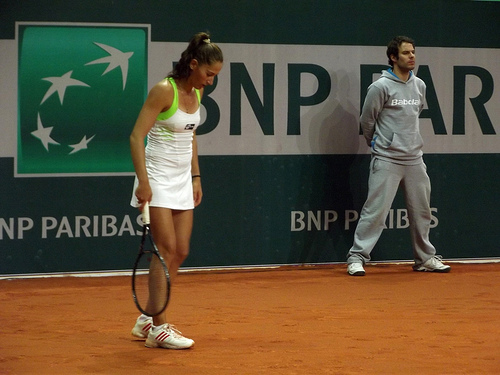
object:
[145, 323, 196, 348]
shoe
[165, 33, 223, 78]
hair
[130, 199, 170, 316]
racket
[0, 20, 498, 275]
advertisement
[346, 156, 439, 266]
pants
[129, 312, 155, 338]
tennis shoe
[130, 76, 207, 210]
dress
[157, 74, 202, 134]
straps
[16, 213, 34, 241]
letter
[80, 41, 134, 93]
white stars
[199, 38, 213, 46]
scurnchie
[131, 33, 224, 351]
woman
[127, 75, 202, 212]
dress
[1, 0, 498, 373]
tennis court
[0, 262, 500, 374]
dirt surface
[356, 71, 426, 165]
shirt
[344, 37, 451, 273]
man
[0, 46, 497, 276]
wall